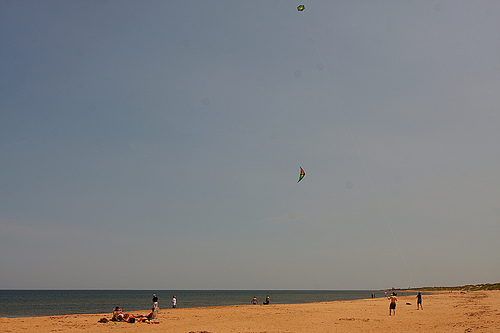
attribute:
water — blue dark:
[0, 288, 428, 323]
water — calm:
[0, 286, 439, 315]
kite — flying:
[273, 146, 359, 211]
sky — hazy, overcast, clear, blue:
[5, 6, 499, 284]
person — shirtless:
[385, 292, 399, 316]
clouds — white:
[72, 32, 130, 93]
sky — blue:
[176, 17, 498, 188]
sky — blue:
[60, 32, 462, 187]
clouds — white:
[376, 55, 420, 95]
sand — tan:
[244, 307, 341, 324]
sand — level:
[278, 300, 345, 327]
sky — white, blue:
[307, 30, 463, 145]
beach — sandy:
[0, 289, 500, 331]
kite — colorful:
[289, 162, 311, 185]